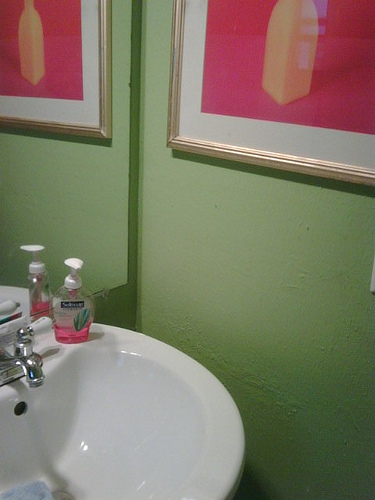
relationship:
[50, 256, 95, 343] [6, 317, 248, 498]
soap on sink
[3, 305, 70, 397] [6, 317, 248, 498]
faucet on sink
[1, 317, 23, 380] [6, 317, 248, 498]
toothpaste on sink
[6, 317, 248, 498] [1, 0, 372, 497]
sink against wall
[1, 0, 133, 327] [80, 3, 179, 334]
mirror on wall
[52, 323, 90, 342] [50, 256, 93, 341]
soap in bottle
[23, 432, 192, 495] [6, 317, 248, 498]
drain in sink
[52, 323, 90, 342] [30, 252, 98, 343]
soap in bottle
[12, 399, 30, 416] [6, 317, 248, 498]
air hole in sink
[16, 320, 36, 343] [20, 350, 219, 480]
handle on sink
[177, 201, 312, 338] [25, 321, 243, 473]
wall near sink